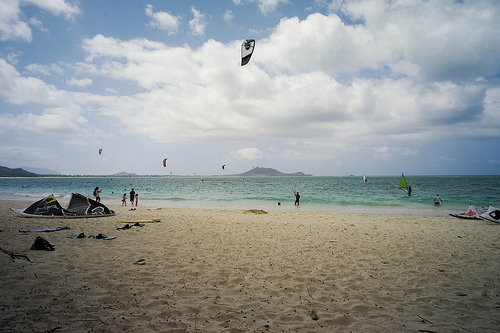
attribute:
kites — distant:
[99, 146, 230, 171]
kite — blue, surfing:
[239, 35, 256, 67]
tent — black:
[14, 191, 116, 219]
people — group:
[89, 185, 141, 206]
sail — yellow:
[395, 169, 411, 189]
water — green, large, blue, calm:
[0, 174, 500, 222]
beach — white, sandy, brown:
[2, 197, 500, 330]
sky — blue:
[1, 1, 500, 174]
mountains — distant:
[232, 166, 320, 179]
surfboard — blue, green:
[14, 222, 70, 235]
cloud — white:
[256, 10, 385, 71]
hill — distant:
[113, 169, 142, 177]